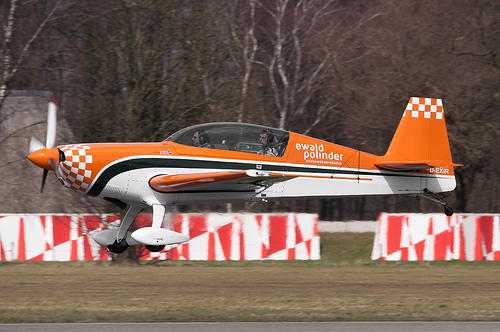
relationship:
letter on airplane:
[309, 142, 315, 153] [24, 96, 460, 255]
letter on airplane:
[302, 150, 308, 160] [24, 96, 460, 255]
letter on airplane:
[308, 149, 316, 163] [24, 96, 460, 255]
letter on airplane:
[322, 150, 329, 160] [24, 96, 460, 255]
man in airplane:
[190, 123, 210, 146] [24, 96, 460, 255]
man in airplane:
[254, 125, 279, 160] [24, 96, 460, 255]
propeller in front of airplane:
[26, 89, 81, 196] [24, 96, 460, 255]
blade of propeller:
[40, 93, 60, 151] [24, 90, 463, 252]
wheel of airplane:
[90, 221, 128, 252] [24, 96, 460, 255]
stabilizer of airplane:
[386, 90, 460, 155] [24, 96, 460, 255]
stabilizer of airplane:
[379, 159, 465, 178] [24, 96, 460, 255]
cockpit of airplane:
[162, 119, 291, 159] [24, 96, 460, 255]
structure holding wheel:
[130, 203, 187, 255] [145, 241, 166, 251]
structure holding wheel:
[88, 227, 136, 251] [106, 237, 128, 254]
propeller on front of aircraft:
[26, 89, 80, 208] [22, 84, 464, 256]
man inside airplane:
[254, 130, 277, 154] [24, 96, 460, 255]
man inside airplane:
[190, 123, 212, 147] [24, 96, 460, 255]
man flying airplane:
[254, 125, 279, 160] [24, 96, 460, 255]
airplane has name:
[24, 96, 460, 255] [289, 137, 347, 165]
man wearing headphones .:
[190, 123, 212, 147] [188, 126, 208, 138]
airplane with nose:
[24, 96, 460, 255] [29, 128, 95, 190]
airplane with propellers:
[24, 96, 460, 255] [15, 91, 164, 268]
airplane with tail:
[24, 96, 460, 255] [378, 83, 466, 203]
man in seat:
[190, 123, 212, 147] [253, 125, 292, 150]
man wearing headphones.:
[190, 123, 212, 147] [188, 123, 276, 149]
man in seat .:
[190, 123, 212, 147] [260, 123, 285, 152]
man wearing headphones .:
[190, 123, 212, 147] [192, 123, 291, 138]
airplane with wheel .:
[24, 96, 460, 255] [88, 214, 188, 269]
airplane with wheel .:
[24, 96, 460, 255] [103, 232, 192, 262]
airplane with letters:
[24, 96, 460, 255] [296, 140, 454, 180]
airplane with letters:
[24, 80, 460, 247] [429, 170, 449, 176]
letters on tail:
[429, 170, 449, 176] [375, 87, 464, 201]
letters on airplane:
[294, 139, 337, 162] [24, 96, 460, 255]